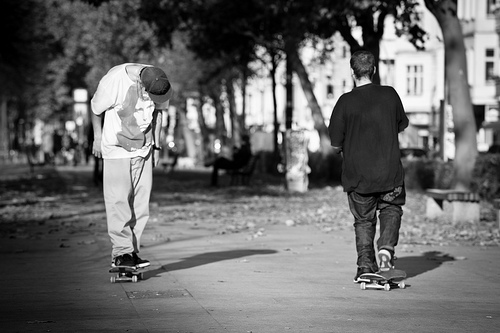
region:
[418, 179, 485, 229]
concrete and wood park bench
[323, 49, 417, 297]
male skateboarder in black shirt and jeans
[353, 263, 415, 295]
skateboard on pavement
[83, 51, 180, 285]
male skateboarder skating on wide park sidewalk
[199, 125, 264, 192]
man sitting on park bench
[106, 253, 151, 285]
skateboard rolling down sidewalk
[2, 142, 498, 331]
gray concrete sidewalk in park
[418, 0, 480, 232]
tree trunk growing along sidewalk in park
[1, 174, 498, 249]
leaves scattered all over sidewalk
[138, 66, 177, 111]
baseball hat on man's head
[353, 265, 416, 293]
using a skateboard as transportation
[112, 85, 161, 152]
Tshirt with Jim Morrison of The Doors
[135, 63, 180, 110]
man is wearing a ball cap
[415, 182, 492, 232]
park bench along a walkway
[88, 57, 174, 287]
skateboarder rolling along a sidewalk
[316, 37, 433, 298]
man pushing off a skateboard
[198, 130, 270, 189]
person sitting on a park bench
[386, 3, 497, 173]
buildings across the street from a park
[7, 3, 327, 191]
line of trees in a park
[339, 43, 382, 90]
guy with a short haircut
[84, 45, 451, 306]
two people on skateboards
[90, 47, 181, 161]
man in white shirt with face on it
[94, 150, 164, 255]
man in khaki pants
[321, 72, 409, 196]
man in black shirt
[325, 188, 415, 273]
man in blue jeans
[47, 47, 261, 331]
mans shadow on ground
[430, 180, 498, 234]
cement bench in photograph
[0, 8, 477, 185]
tree lined street in photograph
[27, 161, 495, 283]
many leaves on side walk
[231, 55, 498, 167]
white buildings with windows in background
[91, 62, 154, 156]
a Jim Morrison t-shirt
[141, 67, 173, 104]
the skateboarder is wearing a baseball cap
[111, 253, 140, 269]
a pair of skateboard shoes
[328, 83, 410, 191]
this skateboarder is wearing a dark t-shirt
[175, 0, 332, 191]
trees are lining the sidewalk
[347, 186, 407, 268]
the skateboarder is wearing blue jeans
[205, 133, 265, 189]
someone sitting on a park bench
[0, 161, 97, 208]
the trees are blocking the sun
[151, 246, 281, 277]
a shadow formed of the skateboarder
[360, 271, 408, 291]
a skateboard with white wheels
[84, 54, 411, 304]
two people are skateboarding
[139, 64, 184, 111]
he has a cap on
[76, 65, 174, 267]
he is wearing light color clothing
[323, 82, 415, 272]
he is wearing dark color clothing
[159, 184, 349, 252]
there are leaves on the ground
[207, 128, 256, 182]
someone sitting on a bench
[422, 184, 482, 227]
an empty bench on the ground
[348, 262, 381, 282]
one foot on the ground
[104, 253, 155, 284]
both feet on the skateboard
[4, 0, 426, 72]
the trees hang over the ground